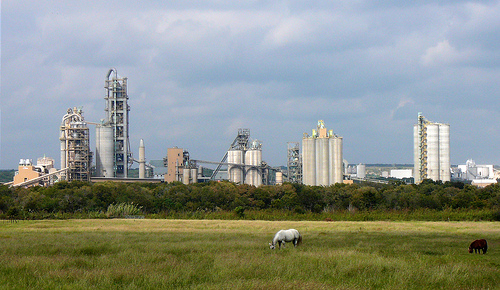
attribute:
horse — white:
[267, 227, 304, 250]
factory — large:
[0, 64, 499, 209]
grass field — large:
[0, 214, 499, 287]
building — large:
[261, 123, 497, 220]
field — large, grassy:
[2, 215, 498, 289]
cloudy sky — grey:
[6, 2, 498, 172]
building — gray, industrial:
[301, 117, 342, 187]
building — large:
[94, 66, 132, 183]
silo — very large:
[245, 129, 264, 189]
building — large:
[299, 118, 346, 187]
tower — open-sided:
[18, 77, 133, 179]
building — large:
[222, 129, 263, 192]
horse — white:
[266, 228, 303, 255]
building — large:
[452, 157, 498, 184]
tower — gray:
[95, 68, 142, 183]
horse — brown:
[467, 237, 489, 256]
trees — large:
[0, 178, 499, 218]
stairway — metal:
[416, 112, 431, 184]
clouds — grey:
[148, 11, 268, 71]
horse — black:
[467, 240, 487, 256]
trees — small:
[4, 166, 496, 217]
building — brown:
[165, 145, 192, 184]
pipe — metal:
[112, 74, 117, 119]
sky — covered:
[105, 12, 498, 118]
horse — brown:
[462, 236, 486, 263]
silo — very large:
[191, 127, 296, 212]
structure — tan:
[160, 146, 184, 183]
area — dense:
[6, 176, 484, 223]